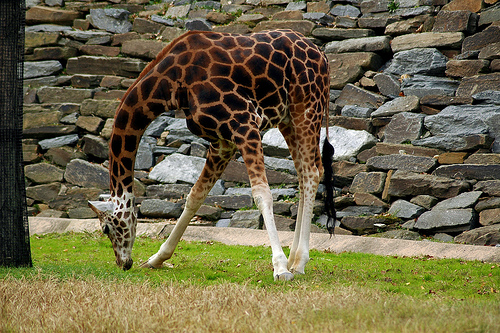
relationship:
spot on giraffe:
[209, 59, 232, 79] [87, 30, 334, 282]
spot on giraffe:
[243, 52, 269, 75] [87, 30, 334, 282]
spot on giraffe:
[270, 34, 294, 57] [87, 30, 334, 282]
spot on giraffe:
[159, 67, 184, 81] [87, 30, 334, 282]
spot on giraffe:
[251, 41, 273, 58] [87, 30, 334, 282]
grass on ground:
[0, 233, 500, 331] [0, 215, 500, 331]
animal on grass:
[87, 27, 340, 287] [3, 226, 498, 322]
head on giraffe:
[88, 189, 136, 270] [87, 30, 334, 282]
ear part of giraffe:
[89, 196, 105, 224] [87, 30, 334, 282]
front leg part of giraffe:
[239, 144, 286, 281] [87, 30, 334, 282]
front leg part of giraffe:
[153, 153, 233, 263] [87, 30, 334, 282]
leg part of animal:
[292, 109, 320, 278] [87, 27, 340, 287]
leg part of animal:
[280, 118, 302, 269] [87, 27, 340, 287]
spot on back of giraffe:
[182, 34, 214, 54] [87, 30, 334, 282]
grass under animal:
[271, 283, 438, 312] [87, 27, 340, 287]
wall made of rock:
[339, 13, 491, 200] [354, 47, 411, 117]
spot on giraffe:
[264, 57, 287, 87] [234, 47, 281, 89]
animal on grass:
[87, 27, 337, 283] [0, 233, 500, 331]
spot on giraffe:
[233, 33, 255, 52] [87, 30, 334, 282]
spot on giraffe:
[222, 92, 247, 110] [87, 30, 334, 282]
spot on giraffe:
[267, 62, 284, 86] [87, 30, 334, 282]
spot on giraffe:
[234, 35, 256, 45] [87, 30, 334, 282]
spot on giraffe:
[292, 55, 307, 73] [87, 30, 334, 282]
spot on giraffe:
[192, 81, 220, 103] [87, 30, 334, 282]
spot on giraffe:
[252, 39, 273, 59] [88, 9, 347, 281]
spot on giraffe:
[198, 102, 232, 124] [87, 30, 334, 282]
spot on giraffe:
[188, 81, 220, 106] [87, 30, 334, 282]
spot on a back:
[238, 54, 276, 89] [154, 27, 330, 119]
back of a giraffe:
[154, 27, 330, 119] [87, 30, 334, 282]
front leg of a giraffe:
[143, 138, 232, 268] [87, 30, 334, 282]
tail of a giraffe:
[321, 138, 337, 238] [87, 30, 334, 282]